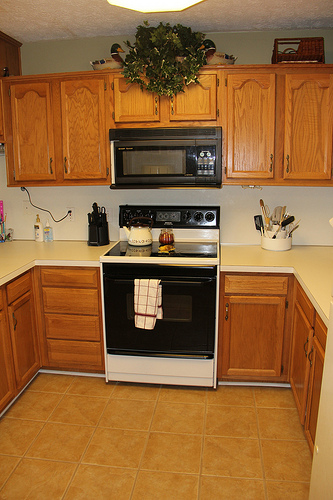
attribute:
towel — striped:
[132, 278, 165, 333]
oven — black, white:
[102, 265, 218, 386]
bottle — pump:
[43, 222, 51, 241]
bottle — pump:
[33, 213, 43, 240]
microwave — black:
[108, 125, 224, 190]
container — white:
[263, 226, 294, 251]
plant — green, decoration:
[120, 24, 208, 99]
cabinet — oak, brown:
[0, 65, 332, 187]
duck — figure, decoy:
[197, 39, 237, 63]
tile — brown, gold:
[0, 370, 311, 497]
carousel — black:
[89, 217, 110, 246]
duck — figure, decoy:
[88, 43, 130, 69]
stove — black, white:
[99, 204, 219, 264]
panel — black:
[117, 205, 218, 231]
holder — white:
[258, 222, 290, 251]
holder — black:
[88, 213, 110, 247]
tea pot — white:
[122, 218, 153, 247]